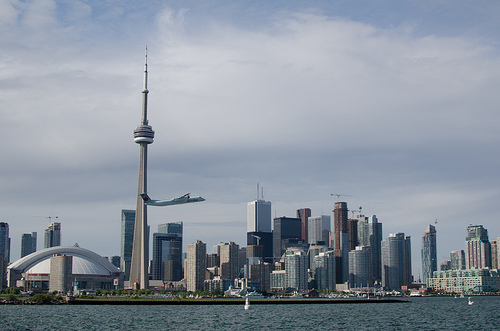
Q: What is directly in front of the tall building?
A: Airplane.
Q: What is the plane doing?
A: Flying over the lake.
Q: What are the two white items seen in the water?
A: Buoys.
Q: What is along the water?
A: City skyline.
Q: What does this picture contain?
A: Skyline of a city.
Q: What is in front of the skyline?
A: Ocean.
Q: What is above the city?
A: White clouds.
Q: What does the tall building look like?
A: Futuristic.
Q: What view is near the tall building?
A: Skyline of city.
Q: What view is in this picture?
A: City skyline near water.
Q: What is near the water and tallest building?
A: Tall buildings.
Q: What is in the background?
A: City.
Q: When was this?
A: Daytime.